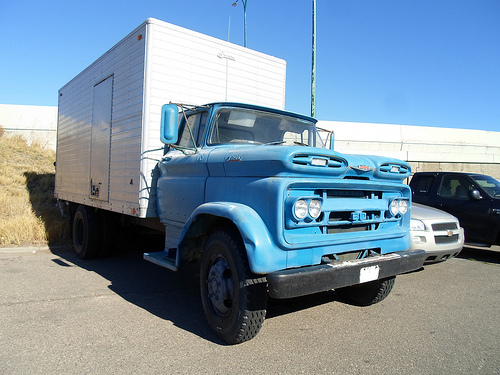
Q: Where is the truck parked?
A: In a parking lot.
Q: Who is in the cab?
A: No one.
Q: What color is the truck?
A: Blue.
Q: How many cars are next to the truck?
A: Two.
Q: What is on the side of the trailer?
A: A door.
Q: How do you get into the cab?
A: There's a step to help.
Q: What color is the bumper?
A: Black.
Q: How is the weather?
A: Clear.